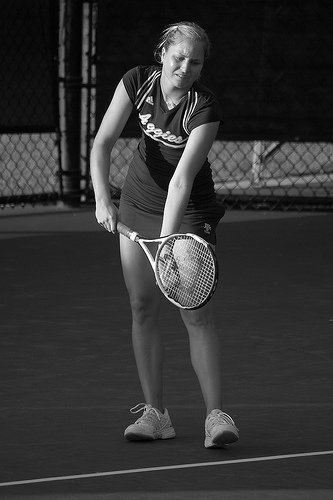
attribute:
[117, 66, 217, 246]
dress — solid color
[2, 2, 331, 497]
picture — black, white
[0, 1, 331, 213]
fence — dark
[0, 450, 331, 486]
line — white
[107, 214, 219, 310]
racket — two tone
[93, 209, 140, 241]
handle — dark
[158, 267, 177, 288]
ball — tennis